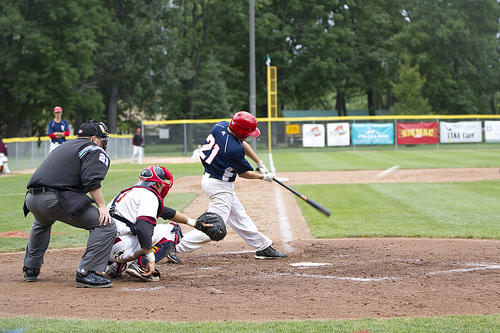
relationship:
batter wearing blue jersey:
[195, 101, 277, 259] [198, 127, 256, 182]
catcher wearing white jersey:
[105, 160, 185, 286] [107, 190, 157, 233]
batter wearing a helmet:
[195, 101, 277, 259] [227, 105, 263, 139]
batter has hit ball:
[195, 101, 277, 259] [376, 163, 401, 185]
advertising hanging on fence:
[298, 124, 499, 150] [15, 112, 495, 166]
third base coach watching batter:
[44, 105, 70, 145] [195, 101, 277, 259]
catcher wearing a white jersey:
[105, 160, 185, 286] [107, 190, 157, 233]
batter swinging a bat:
[195, 101, 277, 259] [273, 176, 333, 220]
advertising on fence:
[298, 124, 499, 150] [15, 112, 495, 166]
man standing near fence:
[129, 127, 150, 165] [15, 112, 495, 166]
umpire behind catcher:
[22, 118, 115, 290] [105, 160, 185, 286]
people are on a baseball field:
[22, 101, 301, 283] [4, 141, 499, 333]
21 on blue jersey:
[200, 134, 222, 171] [198, 127, 256, 182]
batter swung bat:
[195, 101, 277, 259] [273, 176, 333, 220]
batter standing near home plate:
[195, 101, 277, 259] [290, 256, 331, 272]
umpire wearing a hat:
[22, 118, 115, 290] [77, 119, 114, 136]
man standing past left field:
[129, 127, 150, 165] [167, 142, 455, 172]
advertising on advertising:
[298, 124, 499, 150] [298, 117, 499, 149]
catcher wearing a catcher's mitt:
[105, 160, 185, 286] [195, 209, 229, 243]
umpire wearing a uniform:
[22, 118, 115, 290] [24, 134, 111, 272]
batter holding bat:
[195, 101, 277, 259] [273, 176, 333, 220]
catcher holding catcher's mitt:
[105, 160, 185, 286] [195, 209, 229, 243]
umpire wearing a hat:
[22, 118, 115, 290] [77, 119, 96, 136]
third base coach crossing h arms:
[44, 105, 70, 145] [48, 131, 74, 141]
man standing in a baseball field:
[129, 127, 150, 165] [4, 141, 499, 333]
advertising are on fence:
[298, 117, 499, 149] [15, 112, 495, 166]